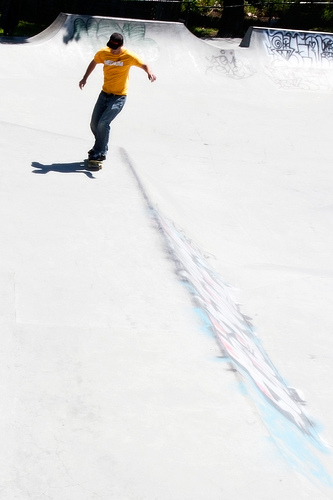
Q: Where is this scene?
A: A skate park.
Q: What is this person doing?
A: Skateboarding.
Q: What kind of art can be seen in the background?
A: Graffiti.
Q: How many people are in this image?
A: One.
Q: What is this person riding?
A: A skateboard.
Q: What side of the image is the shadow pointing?
A: Left.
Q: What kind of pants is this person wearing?
A: Blue jeans.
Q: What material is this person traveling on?
A: Concrete.